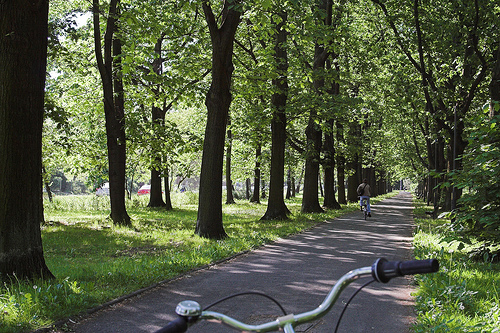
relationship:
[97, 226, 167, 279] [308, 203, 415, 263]
grass near path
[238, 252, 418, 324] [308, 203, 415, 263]
bike on path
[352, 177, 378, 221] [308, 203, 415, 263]
person on path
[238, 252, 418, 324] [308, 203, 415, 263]
bike in path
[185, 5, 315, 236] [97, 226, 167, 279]
trees in grass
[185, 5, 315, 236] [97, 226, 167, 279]
trees on grass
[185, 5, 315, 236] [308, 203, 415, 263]
trees near path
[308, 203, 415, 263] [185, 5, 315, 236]
path below trees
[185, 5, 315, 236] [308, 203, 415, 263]
trees above path